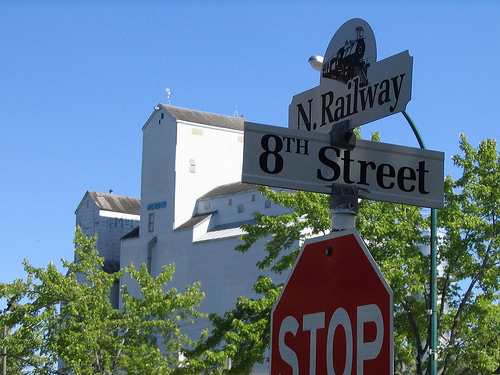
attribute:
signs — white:
[246, 18, 440, 205]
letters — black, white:
[260, 129, 433, 198]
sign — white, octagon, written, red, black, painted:
[263, 231, 395, 374]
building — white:
[49, 83, 489, 374]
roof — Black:
[65, 91, 241, 222]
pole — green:
[407, 116, 464, 372]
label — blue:
[144, 202, 169, 212]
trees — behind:
[4, 223, 269, 374]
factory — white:
[63, 91, 302, 286]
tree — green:
[9, 134, 498, 364]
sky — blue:
[3, 6, 499, 230]